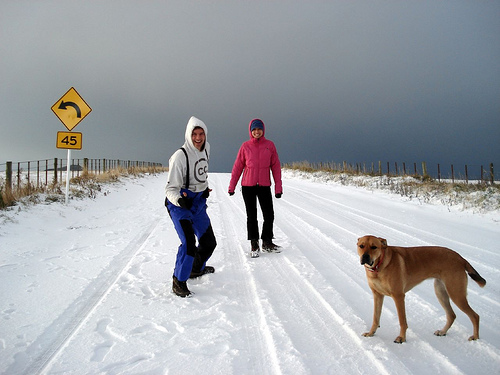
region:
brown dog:
[340, 225, 486, 335]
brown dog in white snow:
[323, 225, 488, 348]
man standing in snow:
[165, 116, 223, 311]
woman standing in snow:
[227, 108, 284, 260]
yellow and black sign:
[45, 88, 87, 133]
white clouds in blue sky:
[80, 9, 132, 76]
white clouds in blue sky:
[310, 38, 387, 116]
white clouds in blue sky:
[191, 12, 242, 76]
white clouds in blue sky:
[397, 3, 465, 105]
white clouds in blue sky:
[337, 92, 414, 159]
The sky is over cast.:
[4, 2, 489, 172]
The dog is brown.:
[335, 216, 485, 336]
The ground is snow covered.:
[19, 158, 490, 372]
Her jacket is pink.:
[220, 113, 291, 195]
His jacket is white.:
[151, 110, 214, 209]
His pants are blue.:
[155, 203, 220, 285]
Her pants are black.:
[228, 175, 279, 245]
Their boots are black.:
[165, 234, 292, 292]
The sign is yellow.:
[46, 91, 93, 158]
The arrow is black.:
[51, 98, 88, 128]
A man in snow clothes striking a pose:
[150, 108, 227, 300]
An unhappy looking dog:
[347, 231, 489, 346]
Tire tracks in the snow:
[32, 218, 160, 371]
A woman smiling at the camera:
[220, 114, 291, 266]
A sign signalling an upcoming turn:
[44, 81, 101, 135]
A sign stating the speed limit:
[46, 130, 88, 201]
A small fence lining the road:
[325, 156, 499, 189]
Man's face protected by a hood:
[181, 115, 210, 157]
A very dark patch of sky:
[305, 75, 498, 177]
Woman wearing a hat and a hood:
[245, 115, 270, 143]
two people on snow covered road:
[152, 98, 289, 297]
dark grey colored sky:
[1, 1, 499, 185]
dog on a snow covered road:
[351, 230, 498, 355]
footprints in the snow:
[6, 232, 243, 374]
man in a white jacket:
[159, 100, 228, 303]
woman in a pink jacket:
[222, 105, 292, 262]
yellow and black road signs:
[50, 78, 92, 152]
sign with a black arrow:
[48, 84, 98, 130]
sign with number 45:
[53, 129, 87, 151]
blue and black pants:
[161, 185, 223, 285]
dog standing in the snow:
[345, 230, 491, 350]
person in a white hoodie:
[162, 108, 222, 304]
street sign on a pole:
[47, 85, 94, 200]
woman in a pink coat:
[225, 111, 293, 263]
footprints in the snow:
[85, 310, 182, 370]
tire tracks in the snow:
[5, 298, 290, 373]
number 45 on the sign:
[54, 130, 85, 150]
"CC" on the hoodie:
[192, 153, 211, 188]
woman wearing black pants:
[225, 115, 285, 256]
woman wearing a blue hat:
[225, 118, 289, 261]